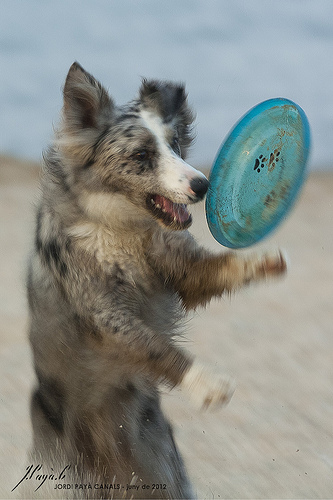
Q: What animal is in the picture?
A: Dog.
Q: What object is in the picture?
A: Frisbee.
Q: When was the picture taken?
A: Daytime.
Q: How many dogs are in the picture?
A: One.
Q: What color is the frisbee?
A: Blue.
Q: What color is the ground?
A: Tan.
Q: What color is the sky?
A: Blue and white.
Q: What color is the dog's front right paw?
A: White.